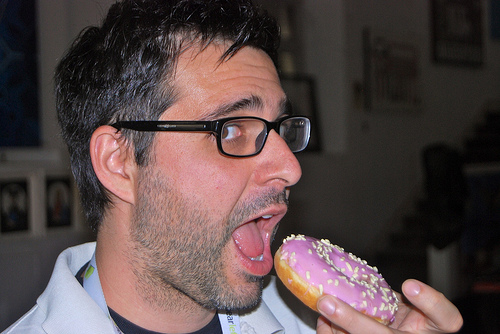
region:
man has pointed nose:
[245, 125, 329, 229]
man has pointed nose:
[252, 127, 300, 204]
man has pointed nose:
[261, 100, 316, 195]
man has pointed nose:
[180, 41, 320, 242]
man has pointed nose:
[231, 87, 302, 225]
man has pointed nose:
[201, 120, 355, 307]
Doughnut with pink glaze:
[277, 221, 404, 324]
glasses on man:
[172, 108, 316, 160]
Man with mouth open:
[227, 188, 289, 276]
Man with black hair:
[48, 8, 275, 165]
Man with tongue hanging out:
[238, 226, 273, 263]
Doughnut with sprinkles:
[276, 230, 401, 325]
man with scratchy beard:
[138, 167, 283, 317]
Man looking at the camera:
[47, 8, 344, 326]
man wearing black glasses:
[107, 106, 312, 156]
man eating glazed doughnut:
[54, 8, 315, 328]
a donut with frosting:
[269, 227, 399, 321]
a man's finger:
[404, 275, 459, 332]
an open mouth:
[217, 192, 294, 279]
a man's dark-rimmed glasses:
[114, 115, 323, 155]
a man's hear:
[82, 115, 143, 207]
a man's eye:
[214, 115, 244, 151]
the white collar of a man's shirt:
[22, 241, 116, 332]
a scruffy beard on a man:
[155, 209, 267, 318]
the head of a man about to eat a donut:
[55, 18, 416, 331]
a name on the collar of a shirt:
[217, 307, 249, 329]